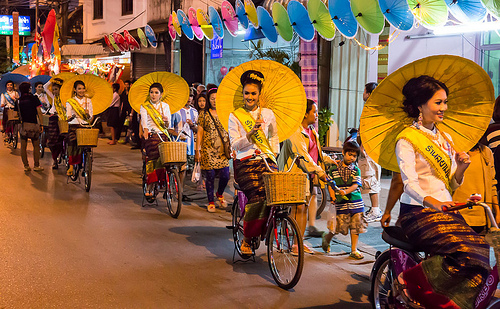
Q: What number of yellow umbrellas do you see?
A: Four.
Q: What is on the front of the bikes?
A: Baskets.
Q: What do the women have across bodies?
A: Banners.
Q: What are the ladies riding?
A: Bicycles.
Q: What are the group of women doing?
A: Riding bikes.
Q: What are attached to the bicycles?
A: Baskets.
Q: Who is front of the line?
A: A girl on a bike.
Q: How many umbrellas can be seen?
A: 7.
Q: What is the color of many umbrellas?
A: Yellow.